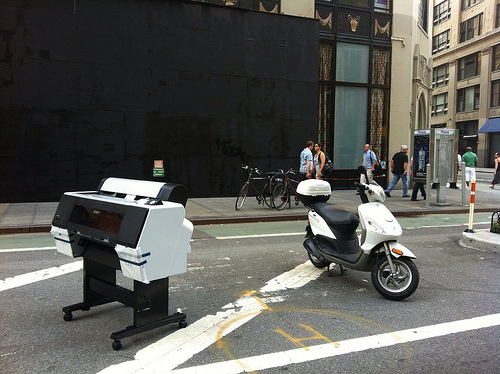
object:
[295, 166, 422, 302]
motorcycle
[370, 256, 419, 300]
wheel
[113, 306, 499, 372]
line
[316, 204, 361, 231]
seat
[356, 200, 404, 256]
guard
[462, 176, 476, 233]
pole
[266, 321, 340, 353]
h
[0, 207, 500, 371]
road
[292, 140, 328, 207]
couple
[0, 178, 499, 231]
sidewalk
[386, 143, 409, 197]
man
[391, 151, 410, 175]
t-shirt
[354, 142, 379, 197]
man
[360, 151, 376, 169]
shirt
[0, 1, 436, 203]
wall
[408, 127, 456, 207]
phone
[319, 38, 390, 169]
window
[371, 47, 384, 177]
curtains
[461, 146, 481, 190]
man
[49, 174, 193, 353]
barbeque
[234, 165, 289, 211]
bicycles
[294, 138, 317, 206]
people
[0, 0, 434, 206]
building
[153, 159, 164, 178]
sign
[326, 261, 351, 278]
kickstand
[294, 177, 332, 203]
trunk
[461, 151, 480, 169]
shirt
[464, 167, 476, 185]
pants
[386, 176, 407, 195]
blue jeans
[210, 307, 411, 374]
circle